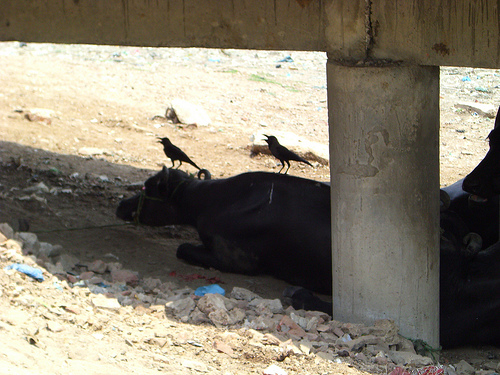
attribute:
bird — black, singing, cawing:
[262, 133, 314, 175]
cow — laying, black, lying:
[117, 167, 499, 351]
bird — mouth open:
[158, 137, 201, 169]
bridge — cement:
[1, 0, 500, 349]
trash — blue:
[196, 284, 225, 299]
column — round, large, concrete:
[326, 62, 440, 354]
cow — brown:
[462, 107, 500, 206]